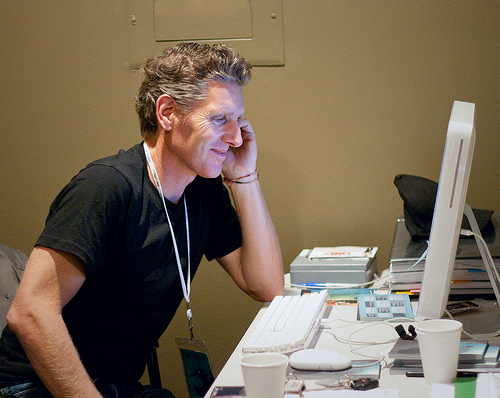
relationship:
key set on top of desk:
[317, 365, 382, 393] [203, 272, 498, 397]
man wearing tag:
[0, 40, 285, 396] [136, 140, 215, 398]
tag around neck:
[136, 140, 215, 398] [140, 127, 204, 200]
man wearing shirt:
[0, 40, 285, 396] [0, 135, 241, 380]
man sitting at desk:
[0, 40, 285, 396] [203, 272, 498, 397]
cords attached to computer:
[313, 305, 484, 368] [241, 99, 481, 355]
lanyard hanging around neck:
[140, 138, 205, 330] [135, 128, 199, 200]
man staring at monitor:
[0, 40, 285, 396] [422, 77, 465, 327]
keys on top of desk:
[318, 375, 383, 390] [379, 367, 425, 393]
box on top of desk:
[287, 241, 380, 286] [207, 254, 496, 396]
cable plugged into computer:
[440, 305, 484, 338] [288, 52, 499, 358]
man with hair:
[0, 40, 285, 396] [135, 40, 254, 131]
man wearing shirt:
[0, 40, 285, 396] [41, 147, 255, 364]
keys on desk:
[315, 375, 383, 390] [198, 239, 498, 396]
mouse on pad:
[287, 346, 358, 373] [280, 355, 388, 395]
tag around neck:
[136, 134, 223, 394] [111, 125, 206, 199]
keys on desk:
[315, 374, 385, 394] [207, 254, 496, 396]